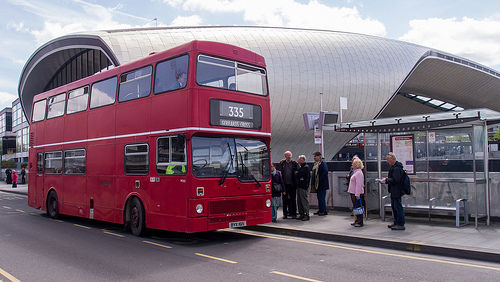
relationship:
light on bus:
[258, 194, 286, 217] [25, 39, 273, 239]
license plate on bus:
[227, 219, 249, 232] [25, 39, 273, 239]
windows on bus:
[29, 137, 185, 181] [25, 39, 273, 239]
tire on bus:
[122, 194, 149, 236] [14, 37, 289, 252]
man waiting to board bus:
[376, 153, 415, 230] [22, 57, 270, 277]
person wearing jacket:
[346, 151, 368, 227] [344, 169, 373, 201]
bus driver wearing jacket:
[164, 151, 189, 174] [162, 160, 190, 180]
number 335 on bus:
[226, 103, 247, 118] [25, 39, 273, 239]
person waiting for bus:
[346, 151, 368, 227] [19, 59, 300, 243]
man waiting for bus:
[376, 153, 415, 230] [19, 59, 300, 243]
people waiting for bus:
[307, 150, 332, 218] [19, 59, 300, 243]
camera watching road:
[323, 112, 335, 126] [0, 181, 500, 281]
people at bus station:
[246, 114, 473, 280] [228, 111, 497, 251]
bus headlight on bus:
[191, 202, 208, 216] [44, 40, 312, 251]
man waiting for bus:
[376, 153, 415, 230] [25, 39, 273, 239]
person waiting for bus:
[346, 151, 368, 227] [25, 39, 273, 239]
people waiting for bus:
[307, 150, 332, 218] [25, 39, 273, 239]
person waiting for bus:
[293, 153, 312, 219] [25, 39, 273, 239]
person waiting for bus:
[277, 150, 300, 220] [25, 39, 273, 239]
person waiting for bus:
[268, 157, 287, 223] [25, 39, 273, 239]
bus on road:
[14, 37, 289, 252] [3, 187, 474, 277]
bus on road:
[25, 39, 273, 239] [3, 174, 495, 279]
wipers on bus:
[209, 133, 274, 195] [25, 39, 273, 239]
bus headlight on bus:
[191, 202, 208, 216] [25, 39, 273, 239]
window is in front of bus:
[191, 135, 238, 171] [25, 39, 273, 239]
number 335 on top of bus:
[226, 103, 247, 118] [25, 39, 273, 239]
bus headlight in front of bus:
[191, 198, 209, 225] [25, 39, 273, 239]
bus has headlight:
[14, 37, 289, 252] [248, 182, 301, 231]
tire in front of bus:
[122, 198, 149, 236] [25, 39, 273, 239]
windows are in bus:
[27, 48, 197, 133] [14, 37, 289, 252]